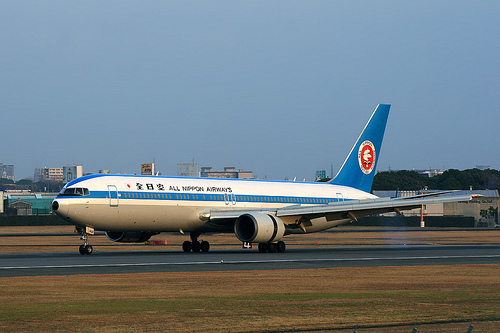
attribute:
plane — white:
[48, 101, 475, 257]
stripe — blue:
[88, 190, 360, 206]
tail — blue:
[325, 102, 397, 194]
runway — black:
[2, 244, 500, 273]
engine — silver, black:
[231, 213, 285, 248]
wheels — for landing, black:
[78, 245, 95, 255]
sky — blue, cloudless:
[1, 2, 499, 183]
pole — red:
[419, 192, 424, 223]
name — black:
[134, 183, 233, 193]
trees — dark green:
[314, 167, 500, 190]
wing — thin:
[198, 193, 484, 246]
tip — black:
[51, 197, 67, 216]